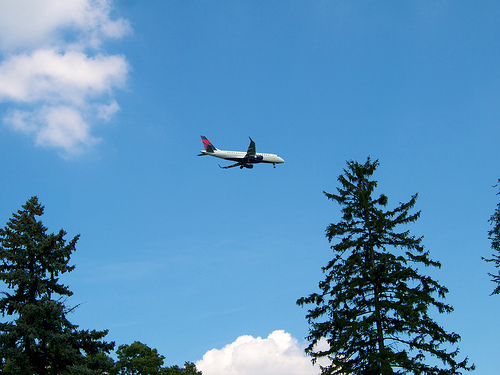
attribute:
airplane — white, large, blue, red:
[196, 136, 285, 173]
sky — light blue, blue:
[1, 2, 499, 373]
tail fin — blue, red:
[200, 136, 214, 152]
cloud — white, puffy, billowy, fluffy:
[193, 327, 349, 374]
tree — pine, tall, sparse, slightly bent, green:
[294, 157, 472, 374]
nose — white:
[273, 153, 286, 166]